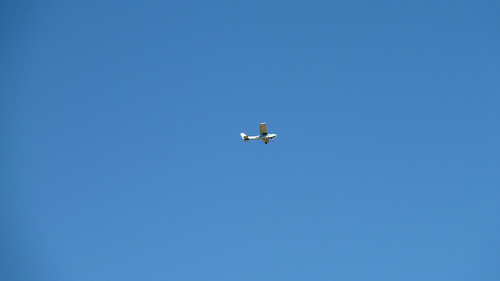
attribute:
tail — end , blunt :
[236, 131, 249, 141]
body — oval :
[243, 123, 271, 142]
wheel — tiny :
[260, 133, 270, 148]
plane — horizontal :
[232, 113, 278, 148]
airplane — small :
[232, 125, 278, 148]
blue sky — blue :
[209, 39, 316, 90]